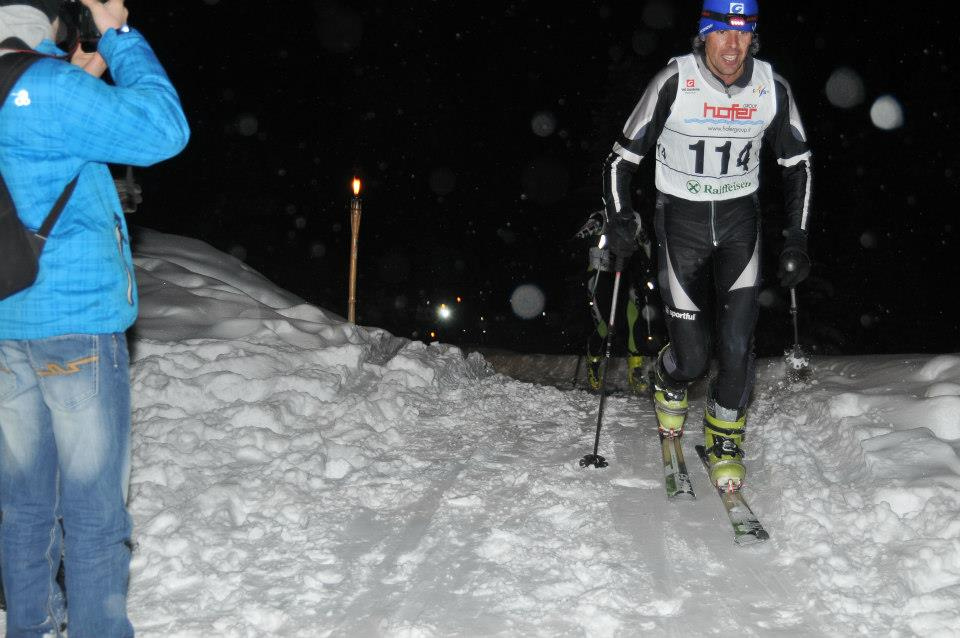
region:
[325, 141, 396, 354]
lit wooden torch light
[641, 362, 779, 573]
pair of ski boots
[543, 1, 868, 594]
a skier on wearing skis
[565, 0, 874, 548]
skier wearing bib 114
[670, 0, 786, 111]
man wearing a blue ski cap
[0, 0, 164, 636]
person wearing a backpack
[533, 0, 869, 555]
two skiers going down a mountain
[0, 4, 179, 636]
person in light blue jacket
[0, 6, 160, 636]
person wearing blue jeans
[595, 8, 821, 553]
man cross-country skiing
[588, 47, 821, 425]
black and white ski suit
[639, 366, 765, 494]
yellow ski boots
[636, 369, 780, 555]
cross country skis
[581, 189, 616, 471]
cross country skiing pole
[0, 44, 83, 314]
black backpack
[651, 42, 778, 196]
white jersey with red and black lettering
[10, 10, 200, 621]
a person wearing a light blue jacket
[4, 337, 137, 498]
faded spots on a pair of jeans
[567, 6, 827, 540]
a man wearing a blue hat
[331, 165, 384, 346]
a lighted torch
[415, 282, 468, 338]
a light shinning in the darkness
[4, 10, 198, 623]
a person wearing a black backpack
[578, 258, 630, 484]
a ski pole in the mans right hand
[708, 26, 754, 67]
Face of a man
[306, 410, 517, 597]
Large patch of snow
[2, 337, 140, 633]
Jeans on a man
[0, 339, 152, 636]
Blue jeans on a man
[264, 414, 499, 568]
Large patch of snow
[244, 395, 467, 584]
Large patch of white snow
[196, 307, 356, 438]
Large patch of snow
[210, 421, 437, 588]
Large patch of white snow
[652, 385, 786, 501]
Yellow and black ski boots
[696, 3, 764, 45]
Blue and white ski helmet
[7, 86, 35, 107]
Small white logo on blue coat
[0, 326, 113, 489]
Blue jeans have faded area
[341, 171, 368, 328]
Fire torch standing near snowy ski path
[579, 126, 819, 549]
Person skiing dressed in black and white outfit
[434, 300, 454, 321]
Small distant light seen in dark sky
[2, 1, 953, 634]
person photographing two people skiing on snow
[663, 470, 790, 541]
skis in the snow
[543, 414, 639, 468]
pole on the snow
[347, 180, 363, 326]
a lamp post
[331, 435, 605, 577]
tracks in the snow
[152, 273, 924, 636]
snow on the hill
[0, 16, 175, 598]
a person in a blue jacket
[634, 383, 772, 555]
the skis on the person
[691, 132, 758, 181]
the number on the jersey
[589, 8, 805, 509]
a person wearing a white jersey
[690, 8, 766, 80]
a man in a blue hat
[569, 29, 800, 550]
two people skiing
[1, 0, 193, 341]
the jacket is blue and gray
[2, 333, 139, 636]
the jeans are blue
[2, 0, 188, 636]
the person is carrying a black backpack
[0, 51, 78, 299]
the backpack is black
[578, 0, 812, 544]
the man is standing on skis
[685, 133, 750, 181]
the number 114 is black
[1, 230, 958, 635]
the snow is white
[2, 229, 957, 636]
the tracks on the white snow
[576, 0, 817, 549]
the man dressed in snow gear